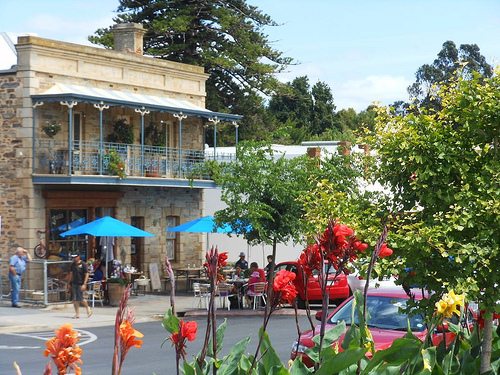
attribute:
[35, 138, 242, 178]
railing — blue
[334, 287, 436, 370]
car — red, parked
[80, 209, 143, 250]
umbrella — blue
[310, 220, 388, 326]
flowers — green, red, yellow, orange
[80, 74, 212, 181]
building — stone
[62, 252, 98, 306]
man — walking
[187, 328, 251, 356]
road — paved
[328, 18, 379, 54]
sky — blue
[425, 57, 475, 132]
tree — green